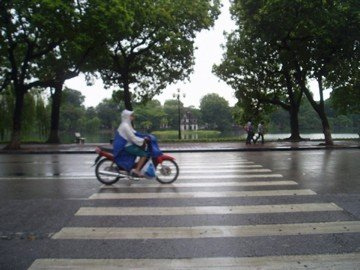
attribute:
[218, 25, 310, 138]
tree — Green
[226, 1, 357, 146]
trees — tall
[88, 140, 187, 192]
motorcycle — red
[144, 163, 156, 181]
bag — white-and-blue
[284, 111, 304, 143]
tree trunk — Brown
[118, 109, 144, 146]
hoodie — white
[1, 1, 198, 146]
trees — Green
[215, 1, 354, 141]
trees — Green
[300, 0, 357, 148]
tree — Green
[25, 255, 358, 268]
line — white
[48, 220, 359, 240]
line — white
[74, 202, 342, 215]
line — white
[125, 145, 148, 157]
pants — green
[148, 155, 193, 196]
wheel — black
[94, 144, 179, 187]
skooter — red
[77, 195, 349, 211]
stripe — white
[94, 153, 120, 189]
wheel — black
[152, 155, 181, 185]
wheel — black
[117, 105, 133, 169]
jacket — white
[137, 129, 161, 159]
tarp — blue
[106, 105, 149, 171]
person — Riding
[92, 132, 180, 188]
motorcycle — red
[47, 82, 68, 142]
tree trunk — brown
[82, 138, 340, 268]
stripes — white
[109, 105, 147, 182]
person — Riding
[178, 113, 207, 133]
white building — small